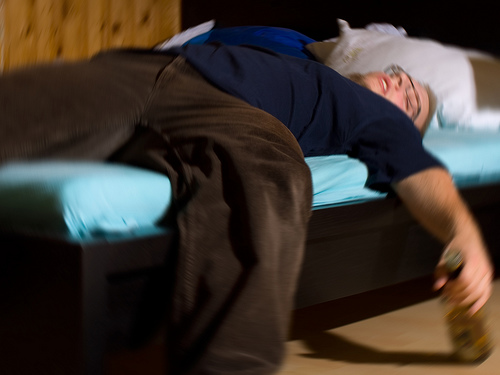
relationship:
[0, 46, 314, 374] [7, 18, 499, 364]
jeans in photo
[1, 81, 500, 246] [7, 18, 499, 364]
bed sheet in photo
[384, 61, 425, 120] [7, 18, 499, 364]
eyeglasses in photo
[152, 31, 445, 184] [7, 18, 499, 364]
shirt in photo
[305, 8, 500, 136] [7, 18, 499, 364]
pillow in photo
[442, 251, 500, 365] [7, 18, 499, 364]
bottle in photo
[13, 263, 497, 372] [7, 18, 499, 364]
floor in photo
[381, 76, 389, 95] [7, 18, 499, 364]
teeth in photo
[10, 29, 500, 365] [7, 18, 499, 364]
man on bed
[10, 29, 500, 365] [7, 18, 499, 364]
man laying on bed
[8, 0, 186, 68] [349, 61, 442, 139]
wall behind head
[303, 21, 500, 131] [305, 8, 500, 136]
case on pillow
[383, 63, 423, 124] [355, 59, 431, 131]
eyeglasses on face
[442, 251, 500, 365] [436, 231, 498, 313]
bottle in hand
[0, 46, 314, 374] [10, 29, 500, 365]
jeans on man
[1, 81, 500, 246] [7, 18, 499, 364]
bed sheet on bed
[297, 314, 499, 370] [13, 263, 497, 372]
shadow top of floor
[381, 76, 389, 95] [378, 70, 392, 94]
teeth in mouth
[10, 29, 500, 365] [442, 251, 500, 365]
man holding bottle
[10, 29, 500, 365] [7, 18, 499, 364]
man sleeping on bed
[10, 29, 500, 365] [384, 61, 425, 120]
man wearing eyeglasses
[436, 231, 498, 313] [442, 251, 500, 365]
hand grasping bottle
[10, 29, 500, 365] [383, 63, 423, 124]
man wearing eyeglasses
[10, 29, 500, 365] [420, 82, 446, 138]
man with hair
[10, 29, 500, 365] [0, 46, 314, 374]
man wearing jeans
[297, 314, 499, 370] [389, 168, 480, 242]
shadow from arm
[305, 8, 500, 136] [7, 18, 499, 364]
pillow on bed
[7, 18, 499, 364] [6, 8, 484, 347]
bed in photo